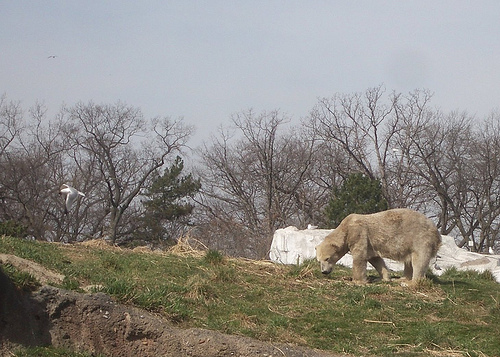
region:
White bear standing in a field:
[305, 201, 458, 288]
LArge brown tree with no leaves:
[4, 98, 29, 242]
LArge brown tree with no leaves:
[31, 102, 56, 222]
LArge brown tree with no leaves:
[58, 94, 104, 239]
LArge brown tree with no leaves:
[93, 107, 131, 258]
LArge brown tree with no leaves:
[129, 122, 186, 243]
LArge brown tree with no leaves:
[192, 158, 239, 248]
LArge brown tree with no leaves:
[207, 105, 274, 236]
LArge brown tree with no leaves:
[273, 112, 318, 226]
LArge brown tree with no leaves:
[315, 87, 392, 222]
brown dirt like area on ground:
[93, 311, 156, 353]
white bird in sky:
[53, 164, 123, 240]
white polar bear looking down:
[311, 233, 358, 292]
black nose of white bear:
[312, 264, 345, 284]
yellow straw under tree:
[173, 233, 220, 260]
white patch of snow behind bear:
[277, 226, 307, 254]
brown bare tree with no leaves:
[243, 121, 295, 193]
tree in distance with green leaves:
[150, 165, 203, 244]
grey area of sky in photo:
[188, 34, 279, 79]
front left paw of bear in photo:
[353, 259, 381, 292]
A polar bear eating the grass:
[319, 208, 442, 284]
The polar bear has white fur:
[314, 207, 439, 283]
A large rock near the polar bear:
[270, 226, 499, 279]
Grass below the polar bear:
[3, 236, 499, 355]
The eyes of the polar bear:
[317, 253, 330, 263]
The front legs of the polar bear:
[351, 243, 393, 281]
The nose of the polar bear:
[321, 266, 332, 276]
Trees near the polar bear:
[2, 93, 499, 264]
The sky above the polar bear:
[0, 1, 496, 221]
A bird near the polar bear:
[58, 182, 86, 209]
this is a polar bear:
[286, 193, 466, 323]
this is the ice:
[270, 209, 498, 294]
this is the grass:
[171, 258, 401, 346]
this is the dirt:
[57, 294, 122, 344]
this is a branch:
[98, 93, 140, 136]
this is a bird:
[55, 171, 102, 220]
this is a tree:
[65, 103, 214, 265]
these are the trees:
[2, 109, 315, 255]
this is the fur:
[357, 213, 417, 251]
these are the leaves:
[173, 197, 185, 214]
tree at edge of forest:
[3, 95, 73, 245]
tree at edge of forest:
[58, 83, 197, 253]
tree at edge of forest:
[127, 143, 205, 254]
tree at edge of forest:
[193, 133, 268, 258]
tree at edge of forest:
[234, 71, 294, 261]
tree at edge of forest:
[267, 133, 324, 235]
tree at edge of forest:
[300, 148, 399, 240]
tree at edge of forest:
[299, 64, 432, 219]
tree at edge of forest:
[400, 100, 460, 247]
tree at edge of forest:
[446, 116, 498, 263]